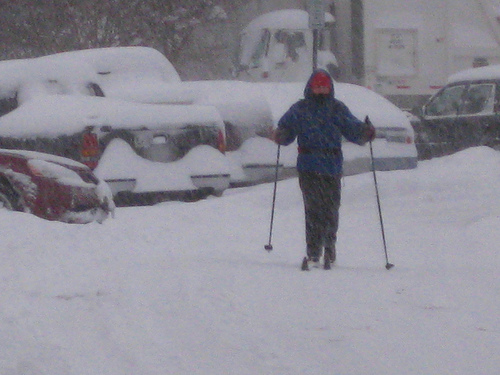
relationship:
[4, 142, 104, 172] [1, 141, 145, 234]
hood of sedan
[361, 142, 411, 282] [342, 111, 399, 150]
ski pole in hand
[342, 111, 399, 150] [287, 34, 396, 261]
hand of skiier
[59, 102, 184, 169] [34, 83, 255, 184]
rear of truck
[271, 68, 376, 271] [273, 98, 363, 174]
person wears jacket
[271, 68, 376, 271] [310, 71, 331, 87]
person wears cap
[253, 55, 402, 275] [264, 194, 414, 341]
person on skis